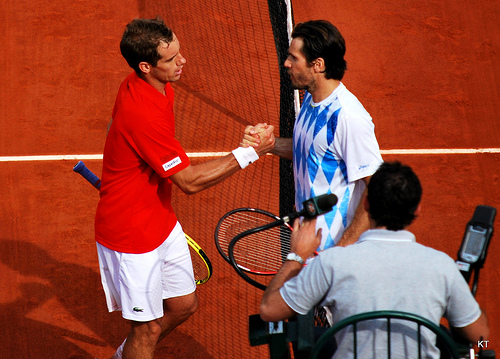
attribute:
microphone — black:
[287, 190, 341, 225]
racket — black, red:
[210, 205, 283, 268]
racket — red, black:
[232, 219, 295, 276]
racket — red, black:
[300, 247, 321, 268]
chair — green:
[326, 297, 448, 354]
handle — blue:
[71, 159, 103, 191]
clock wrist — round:
[264, 236, 311, 269]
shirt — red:
[93, 69, 189, 254]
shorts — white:
[91, 224, 201, 324]